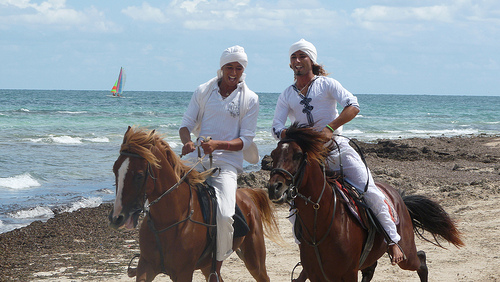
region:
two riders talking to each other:
[105, 23, 445, 261]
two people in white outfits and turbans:
[120, 30, 415, 275]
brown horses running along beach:
[40, 50, 475, 265]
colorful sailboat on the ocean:
[90, 60, 135, 105]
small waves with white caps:
[10, 96, 107, 196]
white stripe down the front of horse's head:
[95, 120, 165, 230]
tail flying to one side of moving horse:
[355, 150, 480, 260]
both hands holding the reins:
[157, 116, 247, 172]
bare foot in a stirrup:
[345, 195, 430, 265]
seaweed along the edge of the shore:
[5, 177, 125, 277]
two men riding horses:
[72, 21, 456, 263]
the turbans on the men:
[198, 46, 340, 66]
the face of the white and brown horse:
[79, 146, 226, 273]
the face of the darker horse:
[256, 126, 326, 228]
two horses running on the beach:
[101, 151, 412, 276]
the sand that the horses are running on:
[453, 198, 495, 268]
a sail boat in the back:
[73, 67, 153, 105]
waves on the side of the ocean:
[14, 121, 71, 176]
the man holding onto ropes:
[181, 136, 225, 162]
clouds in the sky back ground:
[321, 4, 437, 59]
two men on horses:
[86, 24, 466, 279]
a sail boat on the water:
[95, 51, 156, 117]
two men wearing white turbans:
[120, 19, 459, 280]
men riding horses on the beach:
[103, 24, 471, 280]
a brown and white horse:
[87, 106, 202, 280]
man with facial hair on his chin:
[267, 31, 363, 136]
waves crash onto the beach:
[1, 123, 108, 259]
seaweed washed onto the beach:
[405, 124, 498, 191]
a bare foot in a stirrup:
[352, 183, 430, 273]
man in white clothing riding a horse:
[267, 33, 449, 280]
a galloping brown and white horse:
[92, 123, 275, 278]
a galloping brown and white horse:
[256, 120, 466, 280]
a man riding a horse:
[182, 41, 268, 281]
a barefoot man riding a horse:
[268, 31, 415, 270]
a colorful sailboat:
[106, 62, 128, 97]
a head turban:
[212, 43, 254, 68]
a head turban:
[286, 36, 320, 64]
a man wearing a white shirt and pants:
[174, 42, 265, 280]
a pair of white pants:
[303, 138, 402, 247]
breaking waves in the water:
[16, 124, 114, 145]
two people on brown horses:
[122, 27, 432, 271]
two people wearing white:
[192, 25, 353, 142]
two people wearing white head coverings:
[128, 27, 458, 279]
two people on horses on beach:
[7, 34, 437, 279]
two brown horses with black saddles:
[97, 108, 498, 233]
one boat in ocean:
[97, 61, 162, 159]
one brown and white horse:
[80, 121, 180, 271]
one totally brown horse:
[222, 64, 356, 275]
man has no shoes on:
[352, 227, 456, 279]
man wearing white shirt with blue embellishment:
[274, 32, 386, 252]